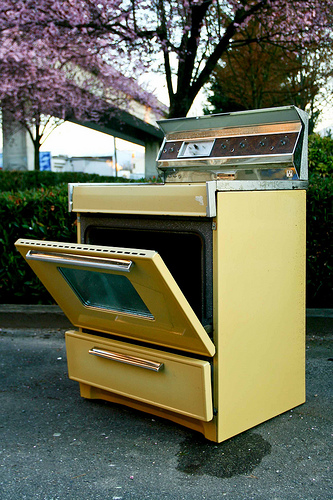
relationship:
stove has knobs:
[5, 100, 323, 457] [156, 140, 222, 162]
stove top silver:
[5, 100, 323, 457] [67, 99, 319, 187]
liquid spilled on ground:
[167, 426, 277, 481] [8, 327, 329, 495]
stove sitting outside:
[5, 100, 323, 457] [2, 4, 331, 498]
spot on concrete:
[167, 426, 277, 481] [8, 327, 329, 495]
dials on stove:
[159, 132, 217, 160] [5, 100, 323, 457]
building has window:
[0, 13, 185, 174] [60, 93, 122, 137]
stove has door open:
[5, 100, 323, 457] [8, 232, 223, 360]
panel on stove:
[154, 123, 300, 163] [5, 100, 323, 457]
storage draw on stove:
[56, 329, 220, 431] [5, 100, 323, 457]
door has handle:
[8, 232, 223, 360] [24, 247, 140, 279]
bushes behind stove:
[1, 163, 68, 243] [5, 100, 323, 457]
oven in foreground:
[8, 232, 223, 360] [9, 180, 224, 493]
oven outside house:
[12, 184, 223, 362] [0, 13, 185, 174]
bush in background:
[308, 132, 331, 267] [308, 99, 331, 197]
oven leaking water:
[5, 100, 323, 457] [167, 426, 277, 481]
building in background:
[0, 13, 185, 174] [3, 5, 331, 126]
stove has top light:
[5, 100, 323, 457] [147, 114, 307, 142]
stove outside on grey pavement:
[5, 100, 323, 457] [8, 327, 329, 495]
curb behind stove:
[6, 296, 68, 332] [5, 100, 323, 457]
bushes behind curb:
[1, 163, 68, 243] [6, 296, 68, 332]